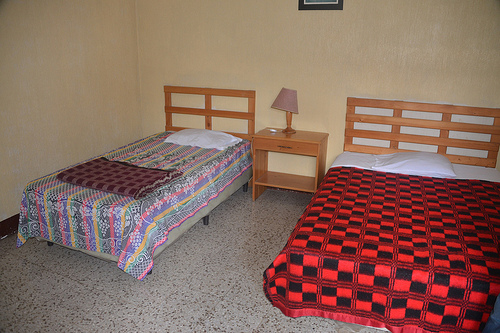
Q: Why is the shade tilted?
A: For light.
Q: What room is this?
A: Bedroom.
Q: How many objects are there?
A: Nine.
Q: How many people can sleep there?
A: Two.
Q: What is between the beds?
A: A Nightstand.